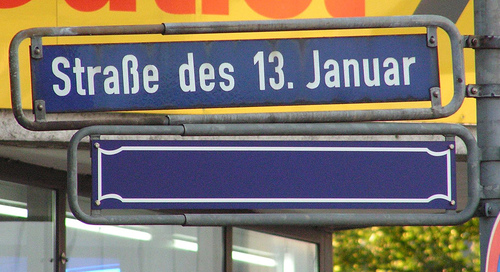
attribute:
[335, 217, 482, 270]
leaves — green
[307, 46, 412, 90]
letters — white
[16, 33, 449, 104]
sign — blue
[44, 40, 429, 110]
text — white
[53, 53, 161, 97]
text — white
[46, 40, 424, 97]
text — white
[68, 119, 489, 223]
signpost — blue in color 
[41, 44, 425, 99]
writing — white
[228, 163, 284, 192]
board — part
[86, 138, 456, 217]
board — part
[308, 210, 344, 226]
metal — part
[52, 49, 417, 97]
text — white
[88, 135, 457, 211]
board — part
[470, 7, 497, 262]
pole — metallic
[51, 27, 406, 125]
sign — blue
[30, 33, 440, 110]
sign — gray and metal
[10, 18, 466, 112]
street sign — blue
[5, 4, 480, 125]
sign — orange and yellow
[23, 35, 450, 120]
sign — blue, road sign, written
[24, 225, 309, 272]
windows — glass 